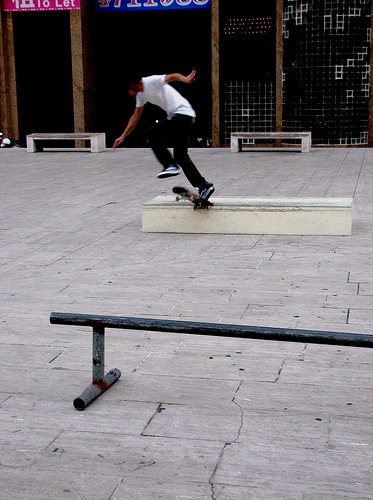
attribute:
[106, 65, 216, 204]
young man — skateboarding, performing trick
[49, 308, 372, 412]
rail — metal, gray, long, here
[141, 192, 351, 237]
ledge — white, rectangular, concrete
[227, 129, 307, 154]
bench — stone, white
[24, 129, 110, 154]
bench — stone, white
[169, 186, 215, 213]
skateboard — black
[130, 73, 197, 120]
shirt — white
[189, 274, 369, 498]
crack — uneven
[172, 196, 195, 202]
wheels — red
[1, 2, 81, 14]
sign — red, pink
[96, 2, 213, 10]
sign — blue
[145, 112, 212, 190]
pants — black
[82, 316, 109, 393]
paint — red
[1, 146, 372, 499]
ground — here